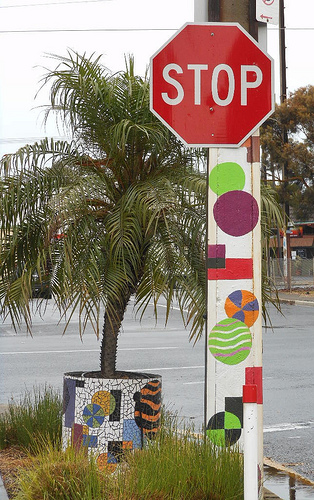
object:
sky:
[0, 0, 314, 144]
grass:
[0, 379, 63, 451]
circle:
[213, 189, 260, 237]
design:
[96, 452, 117, 473]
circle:
[206, 409, 242, 447]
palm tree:
[0, 44, 287, 471]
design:
[82, 404, 104, 429]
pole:
[205, 0, 265, 497]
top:
[148, 21, 278, 145]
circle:
[224, 289, 259, 329]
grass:
[9, 424, 109, 497]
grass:
[119, 419, 244, 500]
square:
[206, 243, 226, 269]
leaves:
[109, 235, 121, 266]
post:
[60, 366, 163, 487]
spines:
[120, 301, 123, 306]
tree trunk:
[98, 290, 132, 379]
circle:
[209, 161, 246, 198]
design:
[205, 244, 253, 280]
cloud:
[1, 0, 45, 30]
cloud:
[266, 0, 311, 104]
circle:
[207, 317, 253, 367]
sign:
[149, 20, 273, 150]